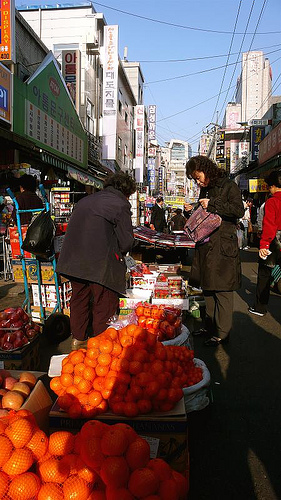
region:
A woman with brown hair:
[52, 172, 141, 351]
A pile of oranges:
[48, 323, 188, 417]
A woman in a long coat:
[185, 155, 244, 346]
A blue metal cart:
[5, 183, 65, 324]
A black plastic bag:
[21, 207, 56, 259]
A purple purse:
[184, 205, 222, 243]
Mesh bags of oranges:
[0, 407, 189, 498]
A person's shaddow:
[219, 309, 279, 497]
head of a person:
[94, 171, 145, 201]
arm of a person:
[106, 204, 143, 242]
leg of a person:
[59, 275, 100, 328]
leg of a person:
[87, 287, 129, 334]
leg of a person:
[209, 277, 248, 325]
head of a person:
[179, 145, 223, 195]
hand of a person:
[195, 197, 227, 215]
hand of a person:
[181, 201, 193, 213]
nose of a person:
[193, 177, 203, 185]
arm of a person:
[252, 203, 278, 252]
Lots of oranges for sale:
[0, 258, 207, 499]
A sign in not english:
[103, 23, 118, 114]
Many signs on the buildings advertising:
[1, 0, 279, 197]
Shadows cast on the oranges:
[49, 306, 204, 499]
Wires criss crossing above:
[89, 0, 280, 160]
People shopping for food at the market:
[13, 154, 279, 355]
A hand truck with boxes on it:
[4, 183, 76, 329]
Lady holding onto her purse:
[180, 195, 225, 244]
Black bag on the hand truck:
[19, 209, 59, 261]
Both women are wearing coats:
[51, 172, 244, 293]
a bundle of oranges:
[1, 409, 192, 498]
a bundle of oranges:
[57, 313, 192, 428]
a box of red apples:
[0, 366, 47, 415]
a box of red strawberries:
[152, 273, 186, 297]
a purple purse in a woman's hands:
[183, 200, 223, 244]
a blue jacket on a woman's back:
[53, 179, 136, 297]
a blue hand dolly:
[5, 182, 72, 343]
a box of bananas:
[9, 252, 67, 286]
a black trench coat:
[184, 169, 249, 297]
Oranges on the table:
[48, 316, 212, 429]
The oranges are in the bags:
[5, 404, 207, 497]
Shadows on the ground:
[196, 328, 280, 495]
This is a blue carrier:
[5, 179, 81, 332]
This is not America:
[9, 58, 279, 240]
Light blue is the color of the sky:
[137, 14, 224, 124]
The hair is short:
[95, 166, 146, 197]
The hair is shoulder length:
[177, 151, 234, 189]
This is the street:
[229, 429, 269, 482]